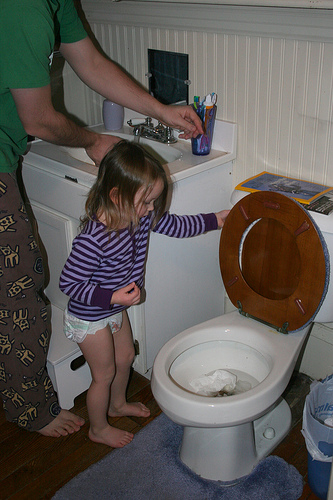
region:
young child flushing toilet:
[58, 138, 331, 484]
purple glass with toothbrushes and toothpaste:
[191, 94, 216, 155]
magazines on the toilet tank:
[237, 172, 331, 212]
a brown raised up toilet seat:
[218, 190, 326, 328]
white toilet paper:
[183, 369, 252, 393]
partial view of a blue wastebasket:
[302, 378, 331, 495]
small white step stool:
[48, 310, 91, 408]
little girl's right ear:
[109, 185, 121, 204]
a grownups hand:
[161, 105, 205, 140]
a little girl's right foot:
[88, 426, 131, 445]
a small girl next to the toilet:
[58, 139, 232, 449]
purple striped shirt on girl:
[57, 209, 218, 321]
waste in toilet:
[189, 370, 247, 395]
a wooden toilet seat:
[218, 190, 327, 329]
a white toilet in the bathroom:
[150, 169, 331, 481]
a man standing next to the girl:
[0, 0, 205, 439]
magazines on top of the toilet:
[237, 169, 332, 214]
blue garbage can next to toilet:
[301, 374, 330, 498]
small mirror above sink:
[145, 45, 190, 103]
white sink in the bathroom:
[21, 99, 235, 194]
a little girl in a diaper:
[61, 143, 230, 448]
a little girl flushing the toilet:
[60, 137, 227, 447]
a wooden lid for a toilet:
[243, 219, 302, 302]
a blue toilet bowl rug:
[57, 410, 299, 498]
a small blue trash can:
[300, 381, 330, 494]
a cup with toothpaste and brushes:
[190, 93, 215, 153]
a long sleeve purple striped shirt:
[57, 212, 216, 321]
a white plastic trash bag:
[302, 377, 332, 462]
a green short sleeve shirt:
[0, 0, 88, 174]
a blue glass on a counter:
[187, 102, 218, 155]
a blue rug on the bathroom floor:
[40, 409, 302, 497]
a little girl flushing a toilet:
[59, 140, 233, 445]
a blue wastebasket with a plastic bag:
[302, 373, 331, 499]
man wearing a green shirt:
[0, 0, 89, 171]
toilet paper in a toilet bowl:
[187, 368, 235, 394]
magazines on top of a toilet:
[233, 169, 330, 216]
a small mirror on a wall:
[148, 47, 188, 105]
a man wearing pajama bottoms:
[1, 172, 60, 429]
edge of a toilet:
[219, 394, 238, 418]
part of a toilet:
[197, 389, 222, 422]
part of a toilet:
[210, 438, 232, 478]